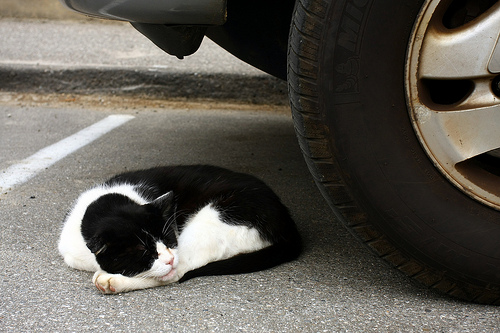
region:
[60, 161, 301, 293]
the cat under the tire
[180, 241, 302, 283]
the tail under the cat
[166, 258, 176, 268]
the pink nose on the cats face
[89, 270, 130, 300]
the paw of the cat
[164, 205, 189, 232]
the white lashes on the face of the cat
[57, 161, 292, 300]
the black and white cat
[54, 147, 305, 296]
the cat laying on the ground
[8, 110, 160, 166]
the white line under car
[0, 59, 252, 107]
the curb along the side of the road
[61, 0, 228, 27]
the bumper on the front of the car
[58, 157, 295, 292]
this is a cat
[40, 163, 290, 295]
the cat is sleeping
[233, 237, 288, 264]
this is the tail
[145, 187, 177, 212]
this is an ear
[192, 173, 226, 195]
the cat is black in color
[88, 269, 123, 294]
this is the leg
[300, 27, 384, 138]
this is the wheel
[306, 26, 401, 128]
the wheel is black in color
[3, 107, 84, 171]
this is the road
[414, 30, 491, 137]
this is a rim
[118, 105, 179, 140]
this is the road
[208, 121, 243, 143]
the road is grey in color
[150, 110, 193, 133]
the road is clean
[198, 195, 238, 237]
the fur is black and white in color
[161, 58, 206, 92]
this is the pavement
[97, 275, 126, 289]
this is the leg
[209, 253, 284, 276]
this is a tail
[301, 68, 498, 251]
this is a wheel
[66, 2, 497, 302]
A car on the street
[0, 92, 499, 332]
The street beneath the cat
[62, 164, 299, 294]
A cat lying on the street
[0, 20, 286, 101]
The sidewalk next to the street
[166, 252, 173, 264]
The nose of the cat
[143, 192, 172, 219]
The left ear of the cat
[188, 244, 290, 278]
The tail of the cat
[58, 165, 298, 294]
A cat lying next to the wheel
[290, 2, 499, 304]
A wheel on the car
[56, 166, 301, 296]
The cat is sleeping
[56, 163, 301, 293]
Black and white cat sleeping.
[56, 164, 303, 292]
Black and white cat sleeping on the ground.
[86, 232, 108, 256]
Right black ear of a sleeping cat.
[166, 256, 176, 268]
Pink nose on a cat's face.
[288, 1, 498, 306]
Large tire beside a cat.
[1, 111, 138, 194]
White parking space line on the road.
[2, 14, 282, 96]
Grey curb by a parked vehicle.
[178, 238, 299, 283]
Black cat's tail.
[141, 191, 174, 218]
A cat's left black ear.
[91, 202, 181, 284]
Head of a white and black cat.